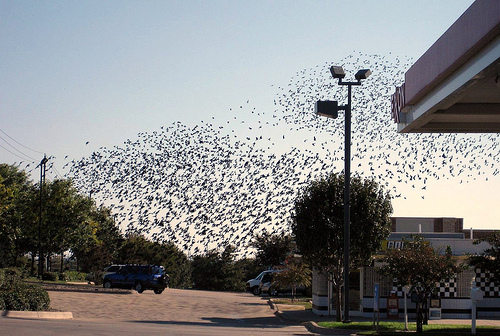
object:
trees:
[0, 163, 120, 268]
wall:
[377, 223, 475, 315]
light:
[319, 66, 370, 189]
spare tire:
[153, 274, 170, 288]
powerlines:
[3, 133, 52, 175]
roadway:
[8, 284, 271, 333]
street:
[163, 292, 233, 332]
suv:
[98, 263, 170, 295]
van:
[246, 270, 281, 297]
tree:
[287, 173, 394, 326]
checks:
[425, 260, 495, 295]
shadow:
[123, 309, 310, 327]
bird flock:
[53, 51, 497, 254]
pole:
[343, 84, 353, 176]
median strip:
[0, 310, 74, 321]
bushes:
[0, 280, 51, 309]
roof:
[389, 0, 496, 136]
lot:
[0, 273, 499, 333]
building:
[367, 224, 496, 283]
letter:
[390, 86, 407, 124]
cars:
[242, 268, 306, 297]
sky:
[6, 4, 496, 242]